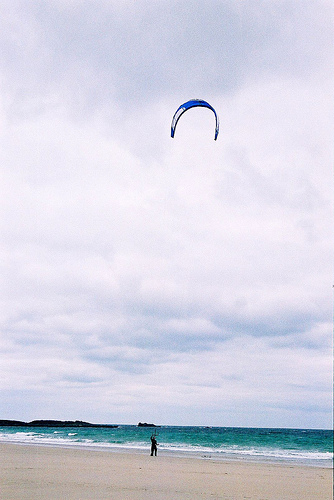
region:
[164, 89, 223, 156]
kite being flown in sky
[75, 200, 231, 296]
overcast day with clouds covering sky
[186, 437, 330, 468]
waves breaking on shore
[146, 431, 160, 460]
person in black looking up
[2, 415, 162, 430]
large rocks in the ocean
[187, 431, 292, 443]
teal water near shore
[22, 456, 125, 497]
clean sand on beach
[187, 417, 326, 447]
horizon can be seen in lower portion of scene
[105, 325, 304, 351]
some blue in the sky can be seen between clouds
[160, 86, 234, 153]
blue and white kite shaped like a boomerang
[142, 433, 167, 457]
Man standing on a beach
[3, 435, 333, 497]
Sand covered beach shore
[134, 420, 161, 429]
Small island in water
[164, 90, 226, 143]
Para sail kite in the air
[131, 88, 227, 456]
Man flying parasail kite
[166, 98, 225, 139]
Blue parasail kite in the air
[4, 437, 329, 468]
Damp sand on the beach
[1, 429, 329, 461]
White spray of water from breaking waves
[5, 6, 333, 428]
Grey overcast sky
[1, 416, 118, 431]
Natural jetty at end of beach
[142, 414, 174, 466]
man flying a kite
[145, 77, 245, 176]
blue kit in the sky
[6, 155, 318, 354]
clear blue sky on beach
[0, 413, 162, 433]
mountains beside the beach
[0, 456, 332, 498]
brown sand on the beach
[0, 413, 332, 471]
clear blue ocean water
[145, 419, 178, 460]
man guiding kit in the sky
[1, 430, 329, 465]
waves crashing against the sand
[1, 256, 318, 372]
white clouds in the sky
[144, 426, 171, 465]
man wearing all black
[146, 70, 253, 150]
object in the air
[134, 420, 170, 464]
person on the beach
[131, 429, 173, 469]
one person in sand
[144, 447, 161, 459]
legs of the person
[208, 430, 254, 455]
water next to man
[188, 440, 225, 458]
white wave coming to the land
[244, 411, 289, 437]
ocean in the background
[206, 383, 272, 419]
clouds in the sky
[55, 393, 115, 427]
rocks in the water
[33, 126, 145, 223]
many clouds in the sky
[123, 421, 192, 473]
LONE PERSON ON BEACH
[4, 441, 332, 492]
BEACH AREA COVERED WITH SAND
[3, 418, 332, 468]
TURQUOISE COLORED OCEAN BEHIND PERSON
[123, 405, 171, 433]
LARGE PROTRUSION IN WATER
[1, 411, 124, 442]
LAND SEEN IN BACKGROUND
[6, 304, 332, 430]
BLUE, CLOUDY SKY IN BACKGROUND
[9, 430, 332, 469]
WAVES BREAKING ON BEACH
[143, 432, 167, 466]
PERSON ON BEACH DRESSED IN DARKCLOTHING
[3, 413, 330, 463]
OCEAN SHOWN AT SKYLINE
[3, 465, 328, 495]
BEACH AREA IS TAN IN COLOR